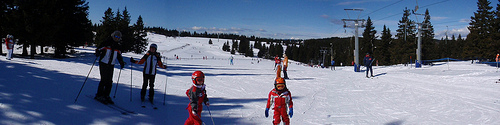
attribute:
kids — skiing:
[183, 66, 297, 124]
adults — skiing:
[96, 29, 166, 103]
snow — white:
[0, 31, 498, 124]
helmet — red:
[192, 68, 205, 84]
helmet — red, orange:
[274, 77, 289, 86]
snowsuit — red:
[182, 86, 209, 124]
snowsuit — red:
[269, 90, 293, 124]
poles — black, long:
[128, 56, 171, 110]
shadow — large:
[1, 63, 302, 124]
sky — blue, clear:
[81, 1, 499, 40]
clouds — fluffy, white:
[329, 17, 474, 39]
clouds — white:
[188, 24, 312, 40]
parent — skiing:
[95, 30, 124, 106]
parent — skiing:
[134, 38, 170, 101]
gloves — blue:
[262, 107, 296, 117]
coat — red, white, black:
[139, 51, 165, 73]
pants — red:
[270, 105, 290, 124]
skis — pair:
[87, 91, 138, 118]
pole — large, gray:
[413, 25, 424, 66]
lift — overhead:
[231, 0, 498, 34]